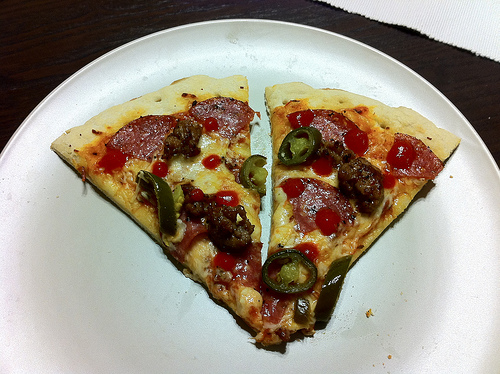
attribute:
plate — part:
[12, 16, 396, 371]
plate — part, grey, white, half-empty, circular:
[22, 19, 484, 353]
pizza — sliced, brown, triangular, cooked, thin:
[90, 70, 461, 347]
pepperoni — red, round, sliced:
[285, 188, 345, 229]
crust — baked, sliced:
[64, 77, 245, 131]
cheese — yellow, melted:
[188, 141, 227, 185]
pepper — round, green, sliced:
[277, 117, 319, 162]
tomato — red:
[286, 103, 372, 152]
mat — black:
[12, 1, 167, 105]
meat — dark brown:
[147, 120, 226, 173]